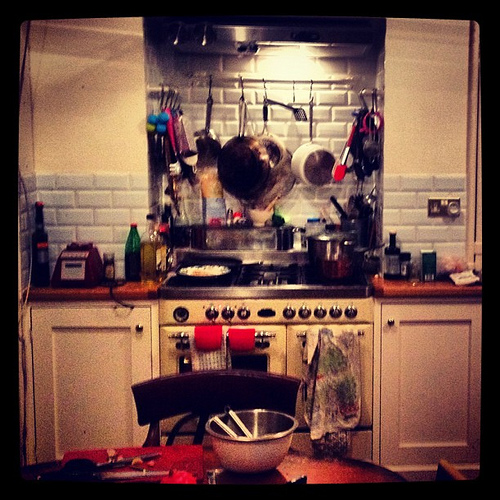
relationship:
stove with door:
[156, 249, 373, 341] [295, 327, 361, 441]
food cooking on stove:
[178, 263, 229, 279] [156, 246, 374, 466]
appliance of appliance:
[51, 242, 105, 287] [47, 241, 105, 287]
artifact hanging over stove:
[195, 95, 221, 159] [156, 246, 374, 466]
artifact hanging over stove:
[291, 97, 336, 188] [156, 246, 374, 466]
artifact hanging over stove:
[217, 102, 271, 202] [156, 246, 374, 466]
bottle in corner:
[32, 199, 50, 286] [24, 22, 48, 287]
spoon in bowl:
[227, 408, 251, 442] [199, 407, 296, 472]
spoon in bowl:
[209, 416, 239, 439] [199, 407, 296, 472]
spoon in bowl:
[228, 410, 252, 439] [205, 409, 299, 472]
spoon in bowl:
[213, 416, 238, 439] [205, 409, 299, 472]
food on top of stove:
[179, 265, 231, 277] [161, 218, 371, 462]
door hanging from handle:
[295, 327, 361, 441] [295, 330, 365, 339]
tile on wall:
[59, 171, 96, 189] [38, 171, 145, 276]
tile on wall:
[96, 174, 128, 187] [38, 171, 145, 276]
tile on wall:
[38, 190, 78, 207] [38, 171, 145, 276]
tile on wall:
[74, 189, 114, 206] [38, 171, 145, 276]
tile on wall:
[116, 190, 146, 206] [38, 171, 145, 276]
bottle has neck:
[32, 201, 50, 286] [30, 205, 45, 231]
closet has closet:
[373, 298, 478, 475] [380, 303, 481, 479]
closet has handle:
[373, 298, 478, 475] [386, 318, 395, 328]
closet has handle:
[380, 303, 481, 479] [386, 318, 395, 328]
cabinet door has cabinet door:
[31, 307, 151, 463] [31, 307, 151, 463]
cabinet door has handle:
[31, 307, 151, 463] [133, 325, 146, 333]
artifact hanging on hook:
[291, 97, 336, 188] [305, 77, 315, 103]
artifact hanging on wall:
[291, 97, 336, 188] [155, 41, 368, 244]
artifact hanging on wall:
[195, 95, 221, 159] [155, 41, 368, 244]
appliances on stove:
[166, 256, 243, 287] [161, 218, 371, 462]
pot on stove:
[305, 230, 357, 278] [161, 218, 371, 462]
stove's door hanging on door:
[160, 325, 373, 435] [283, 324, 371, 431]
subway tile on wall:
[382, 192, 419, 208] [379, 172, 465, 267]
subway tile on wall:
[418, 190, 466, 207] [379, 172, 465, 267]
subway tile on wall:
[432, 172, 468, 190] [379, 172, 465, 267]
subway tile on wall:
[398, 173, 434, 189] [379, 172, 465, 267]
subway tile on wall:
[381, 173, 398, 190] [379, 172, 465, 267]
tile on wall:
[59, 191, 124, 245] [20, 107, 135, 289]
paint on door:
[403, 333, 466, 433] [376, 295, 482, 465]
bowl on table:
[210, 405, 300, 473] [94, 430, 389, 497]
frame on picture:
[463, 30, 498, 456] [34, 16, 493, 476]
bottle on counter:
[32, 201, 50, 286] [18, 259, 168, 321]